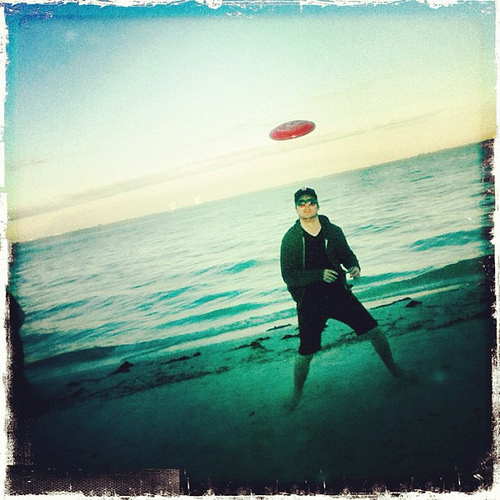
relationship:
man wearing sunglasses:
[270, 187, 420, 413] [294, 194, 319, 209]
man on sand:
[270, 187, 420, 413] [347, 380, 438, 451]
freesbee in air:
[280, 117, 337, 168] [239, 94, 342, 161]